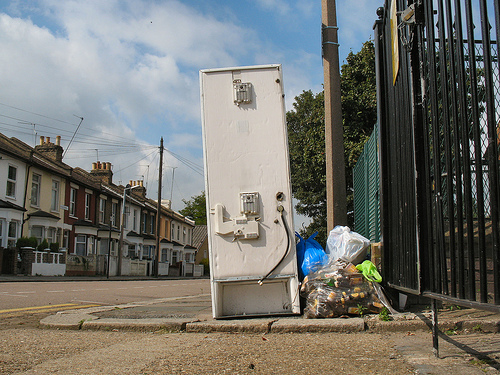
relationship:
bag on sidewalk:
[301, 224, 381, 316] [91, 296, 436, 318]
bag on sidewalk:
[295, 225, 326, 275] [91, 296, 436, 318]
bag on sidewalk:
[326, 221, 370, 262] [91, 296, 436, 318]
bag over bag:
[295, 225, 326, 275] [301, 224, 381, 316]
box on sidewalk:
[199, 63, 302, 319] [91, 296, 436, 318]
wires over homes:
[0, 100, 203, 183] [0, 133, 201, 276]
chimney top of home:
[35, 135, 64, 161] [22, 147, 71, 275]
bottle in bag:
[337, 292, 366, 303] [301, 224, 381, 316]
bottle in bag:
[322, 290, 336, 314] [301, 224, 381, 316]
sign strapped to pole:
[319, 21, 339, 60] [319, 1, 348, 246]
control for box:
[233, 79, 252, 104] [199, 63, 302, 319]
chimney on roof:
[90, 160, 116, 184] [72, 164, 123, 194]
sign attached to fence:
[387, 3, 402, 85] [373, 1, 499, 352]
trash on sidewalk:
[295, 221, 382, 320] [91, 296, 436, 318]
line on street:
[1, 300, 99, 317] [2, 278, 214, 321]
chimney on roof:
[35, 135, 64, 161] [32, 146, 74, 175]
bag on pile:
[295, 225, 326, 275] [295, 221, 382, 320]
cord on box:
[258, 214, 291, 287] [199, 63, 302, 319]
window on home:
[4, 163, 18, 200] [0, 134, 31, 279]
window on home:
[49, 175, 60, 215] [22, 147, 71, 275]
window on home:
[68, 185, 79, 217] [63, 169, 98, 273]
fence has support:
[373, 1, 499, 352] [427, 298, 441, 356]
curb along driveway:
[41, 315, 499, 331] [4, 328, 499, 374]